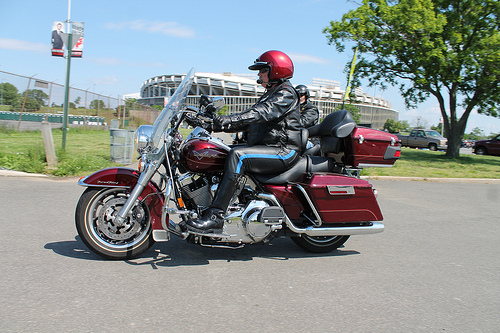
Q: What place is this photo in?
A: It is at the road.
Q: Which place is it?
A: It is a road.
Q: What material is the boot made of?
A: The boot is made of leather.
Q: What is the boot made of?
A: The boot is made of leather.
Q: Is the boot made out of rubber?
A: No, the boot is made of leather.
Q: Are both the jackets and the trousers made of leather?
A: Yes, both the jackets and the trousers are made of leather.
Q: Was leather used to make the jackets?
A: Yes, the jackets are made of leather.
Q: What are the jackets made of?
A: The jackets are made of leather.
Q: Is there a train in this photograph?
A: No, there are no trains.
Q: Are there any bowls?
A: No, there are no bowls.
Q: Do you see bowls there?
A: No, there are no bowls.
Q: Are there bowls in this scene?
A: No, there are no bowls.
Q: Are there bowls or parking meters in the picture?
A: No, there are no bowls or parking meters.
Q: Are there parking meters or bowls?
A: No, there are no bowls or parking meters.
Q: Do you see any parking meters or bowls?
A: No, there are no bowls or parking meters.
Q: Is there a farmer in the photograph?
A: No, there are no farmers.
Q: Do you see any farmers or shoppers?
A: No, there are no farmers or shoppers.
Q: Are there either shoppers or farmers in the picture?
A: No, there are no farmers or shoppers.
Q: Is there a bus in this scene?
A: No, there are no buses.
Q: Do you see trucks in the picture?
A: Yes, there is a truck.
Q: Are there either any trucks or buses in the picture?
A: Yes, there is a truck.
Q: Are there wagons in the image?
A: No, there are no wagons.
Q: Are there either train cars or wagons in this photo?
A: No, there are no wagons or train cars.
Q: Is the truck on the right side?
A: Yes, the truck is on the right of the image.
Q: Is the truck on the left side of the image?
A: No, the truck is on the right of the image.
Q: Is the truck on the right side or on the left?
A: The truck is on the right of the image.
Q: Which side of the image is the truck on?
A: The truck is on the right of the image.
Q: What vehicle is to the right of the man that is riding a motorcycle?
A: The vehicle is a truck.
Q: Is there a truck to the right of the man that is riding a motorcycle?
A: Yes, there is a truck to the right of the man.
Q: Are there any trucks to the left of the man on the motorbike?
A: No, the truck is to the right of the man.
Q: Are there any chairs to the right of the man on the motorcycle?
A: No, there is a truck to the right of the man.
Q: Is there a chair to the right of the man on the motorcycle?
A: No, there is a truck to the right of the man.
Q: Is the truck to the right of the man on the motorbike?
A: Yes, the truck is to the right of the man.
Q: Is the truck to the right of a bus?
A: No, the truck is to the right of the man.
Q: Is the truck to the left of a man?
A: No, the truck is to the right of a man.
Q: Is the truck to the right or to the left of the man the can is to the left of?
A: The truck is to the right of the man.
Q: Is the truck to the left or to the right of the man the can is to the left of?
A: The truck is to the right of the man.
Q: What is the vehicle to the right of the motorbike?
A: The vehicle is a truck.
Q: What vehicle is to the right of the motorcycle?
A: The vehicle is a truck.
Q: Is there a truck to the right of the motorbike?
A: Yes, there is a truck to the right of the motorbike.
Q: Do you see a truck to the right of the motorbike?
A: Yes, there is a truck to the right of the motorbike.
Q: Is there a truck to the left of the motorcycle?
A: No, the truck is to the right of the motorcycle.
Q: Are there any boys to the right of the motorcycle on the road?
A: No, there is a truck to the right of the motorcycle.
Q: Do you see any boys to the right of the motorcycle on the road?
A: No, there is a truck to the right of the motorcycle.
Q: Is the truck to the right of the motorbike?
A: Yes, the truck is to the right of the motorbike.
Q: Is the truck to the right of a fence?
A: No, the truck is to the right of the motorbike.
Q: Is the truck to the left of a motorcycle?
A: No, the truck is to the right of a motorcycle.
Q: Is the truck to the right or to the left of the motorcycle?
A: The truck is to the right of the motorcycle.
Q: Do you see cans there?
A: Yes, there is a can.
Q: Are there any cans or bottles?
A: Yes, there is a can.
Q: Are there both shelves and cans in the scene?
A: No, there is a can but no shelves.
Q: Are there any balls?
A: No, there are no balls.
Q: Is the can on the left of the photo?
A: Yes, the can is on the left of the image.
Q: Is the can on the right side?
A: No, the can is on the left of the image.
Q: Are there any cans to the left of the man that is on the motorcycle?
A: Yes, there is a can to the left of the man.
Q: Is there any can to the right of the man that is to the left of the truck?
A: No, the can is to the left of the man.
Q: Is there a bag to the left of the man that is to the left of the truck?
A: No, there is a can to the left of the man.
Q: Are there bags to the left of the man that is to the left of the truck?
A: No, there is a can to the left of the man.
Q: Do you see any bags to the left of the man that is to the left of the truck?
A: No, there is a can to the left of the man.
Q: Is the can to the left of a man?
A: Yes, the can is to the left of a man.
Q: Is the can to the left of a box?
A: No, the can is to the left of a man.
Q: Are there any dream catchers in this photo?
A: No, there are no dream catchers.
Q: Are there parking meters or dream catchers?
A: No, there are no dream catchers or parking meters.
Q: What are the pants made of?
A: The pants are made of leather.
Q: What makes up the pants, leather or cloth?
A: The pants are made of leather.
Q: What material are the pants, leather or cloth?
A: The pants are made of leather.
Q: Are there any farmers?
A: No, there are no farmers.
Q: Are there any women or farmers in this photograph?
A: No, there are no farmers or women.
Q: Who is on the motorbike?
A: The man is on the motorbike.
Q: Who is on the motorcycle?
A: The man is on the motorbike.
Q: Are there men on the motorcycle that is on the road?
A: Yes, there is a man on the motorcycle.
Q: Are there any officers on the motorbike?
A: No, there is a man on the motorbike.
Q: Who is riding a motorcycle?
A: The man is riding a motorcycle.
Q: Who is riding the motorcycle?
A: The man is riding a motorcycle.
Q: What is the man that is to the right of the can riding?
A: The man is riding a motorcycle.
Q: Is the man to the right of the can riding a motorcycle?
A: Yes, the man is riding a motorcycle.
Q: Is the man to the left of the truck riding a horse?
A: No, the man is riding a motorcycle.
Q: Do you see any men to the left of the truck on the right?
A: Yes, there is a man to the left of the truck.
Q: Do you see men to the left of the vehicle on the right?
A: Yes, there is a man to the left of the truck.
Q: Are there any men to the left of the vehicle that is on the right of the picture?
A: Yes, there is a man to the left of the truck.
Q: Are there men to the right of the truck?
A: No, the man is to the left of the truck.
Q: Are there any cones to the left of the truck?
A: No, there is a man to the left of the truck.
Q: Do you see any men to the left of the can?
A: No, the man is to the right of the can.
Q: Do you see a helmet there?
A: Yes, there is a helmet.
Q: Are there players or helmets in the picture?
A: Yes, there is a helmet.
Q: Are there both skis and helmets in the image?
A: No, there is a helmet but no skis.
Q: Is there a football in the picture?
A: No, there are no footballs.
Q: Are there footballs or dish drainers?
A: No, there are no footballs or dish drainers.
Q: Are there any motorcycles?
A: Yes, there is a motorcycle.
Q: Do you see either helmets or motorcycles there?
A: Yes, there is a motorcycle.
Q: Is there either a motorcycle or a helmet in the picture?
A: Yes, there is a motorcycle.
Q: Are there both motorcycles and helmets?
A: Yes, there are both a motorcycle and a helmet.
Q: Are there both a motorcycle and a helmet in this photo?
A: Yes, there are both a motorcycle and a helmet.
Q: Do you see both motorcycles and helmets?
A: Yes, there are both a motorcycle and a helmet.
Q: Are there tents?
A: No, there are no tents.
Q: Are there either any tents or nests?
A: No, there are no tents or nests.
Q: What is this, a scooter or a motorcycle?
A: This is a motorcycle.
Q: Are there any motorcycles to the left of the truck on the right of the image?
A: Yes, there is a motorcycle to the left of the truck.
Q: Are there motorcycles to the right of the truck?
A: No, the motorcycle is to the left of the truck.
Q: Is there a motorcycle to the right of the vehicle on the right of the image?
A: No, the motorcycle is to the left of the truck.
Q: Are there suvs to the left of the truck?
A: No, there is a motorcycle to the left of the truck.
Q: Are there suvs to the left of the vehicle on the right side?
A: No, there is a motorcycle to the left of the truck.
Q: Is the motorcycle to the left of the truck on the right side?
A: Yes, the motorcycle is to the left of the truck.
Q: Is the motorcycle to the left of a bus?
A: No, the motorcycle is to the left of the truck.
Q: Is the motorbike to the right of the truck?
A: No, the motorbike is to the left of the truck.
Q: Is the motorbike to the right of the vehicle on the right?
A: No, the motorbike is to the left of the truck.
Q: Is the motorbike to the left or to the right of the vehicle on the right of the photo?
A: The motorbike is to the left of the truck.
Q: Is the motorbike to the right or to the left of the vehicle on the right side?
A: The motorbike is to the left of the truck.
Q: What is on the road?
A: The motorbike is on the road.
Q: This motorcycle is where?
A: The motorcycle is on the road.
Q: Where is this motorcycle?
A: The motorcycle is on the road.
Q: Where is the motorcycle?
A: The motorcycle is on the road.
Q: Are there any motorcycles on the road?
A: Yes, there is a motorcycle on the road.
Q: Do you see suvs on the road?
A: No, there is a motorcycle on the road.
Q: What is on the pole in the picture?
A: The sign is on the pole.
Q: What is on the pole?
A: The sign is on the pole.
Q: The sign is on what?
A: The sign is on the pole.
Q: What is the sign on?
A: The sign is on the pole.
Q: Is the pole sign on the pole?
A: Yes, the sign is on the pole.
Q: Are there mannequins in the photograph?
A: No, there are no mannequins.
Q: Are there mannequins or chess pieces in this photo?
A: No, there are no mannequins or chess pieces.